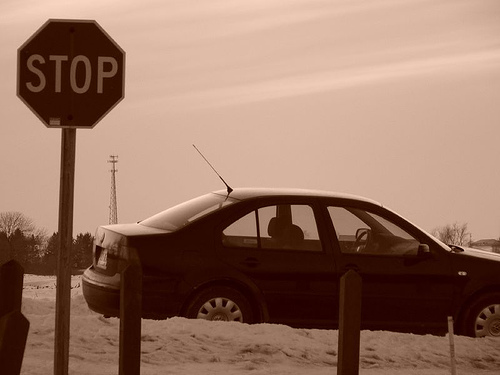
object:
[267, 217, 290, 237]
headrest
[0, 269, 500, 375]
snow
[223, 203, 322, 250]
window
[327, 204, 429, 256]
window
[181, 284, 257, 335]
wheel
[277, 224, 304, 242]
headrest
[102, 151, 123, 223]
tower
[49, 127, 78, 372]
pole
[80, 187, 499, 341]
car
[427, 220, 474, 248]
tree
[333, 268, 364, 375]
pole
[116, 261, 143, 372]
pole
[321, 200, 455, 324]
passenger door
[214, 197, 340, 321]
door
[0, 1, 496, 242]
sky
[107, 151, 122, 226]
electric post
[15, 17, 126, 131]
stop sign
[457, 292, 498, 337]
wheel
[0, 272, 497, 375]
ground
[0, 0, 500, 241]
clouds